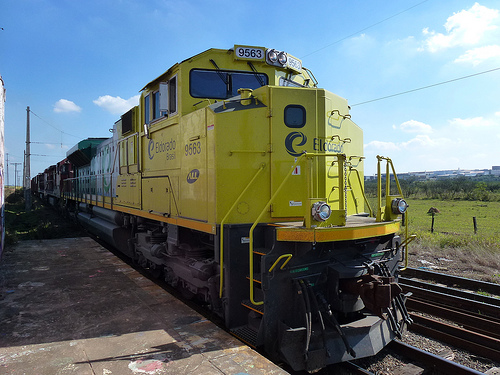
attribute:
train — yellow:
[5, 44, 404, 246]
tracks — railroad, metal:
[327, 259, 499, 374]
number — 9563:
[184, 139, 205, 153]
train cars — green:
[64, 144, 102, 211]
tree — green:
[417, 172, 499, 204]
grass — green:
[383, 179, 493, 239]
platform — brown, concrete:
[15, 238, 281, 374]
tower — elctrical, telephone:
[23, 105, 36, 212]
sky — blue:
[3, 1, 499, 176]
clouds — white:
[421, 4, 499, 67]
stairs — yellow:
[243, 228, 272, 311]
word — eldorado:
[157, 135, 181, 156]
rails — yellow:
[220, 152, 277, 301]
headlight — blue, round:
[308, 204, 331, 226]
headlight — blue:
[395, 192, 409, 216]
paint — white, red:
[36, 259, 141, 348]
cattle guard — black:
[292, 300, 418, 359]